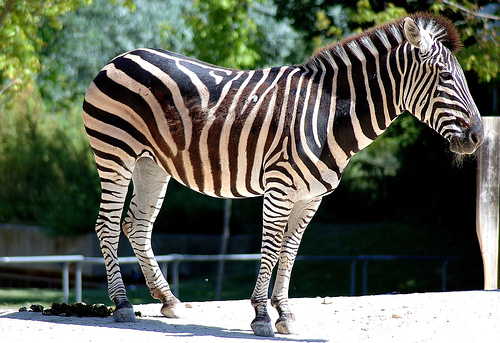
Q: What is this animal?
A: Zebra.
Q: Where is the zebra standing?
A: Ground.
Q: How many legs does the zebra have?
A: Four.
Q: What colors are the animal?
A: Black and white.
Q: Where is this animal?
A: Zoo.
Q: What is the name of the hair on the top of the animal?
A: Mane.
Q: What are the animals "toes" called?
A: Hooves.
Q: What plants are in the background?
A: Treees.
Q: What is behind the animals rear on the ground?
A: Poop.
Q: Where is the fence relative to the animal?
A: Behind.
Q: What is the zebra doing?
A: Standing.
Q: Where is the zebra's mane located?
A: The zebra's mane is located on top and runs along the back.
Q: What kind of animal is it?
A: Zebra.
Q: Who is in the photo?
A: A zebra.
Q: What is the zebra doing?
A: Standing.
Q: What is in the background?
A: Trees.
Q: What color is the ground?
A: Gray.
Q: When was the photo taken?
A: Daytime.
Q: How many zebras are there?
A: One.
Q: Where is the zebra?
A: Standing on concrete.